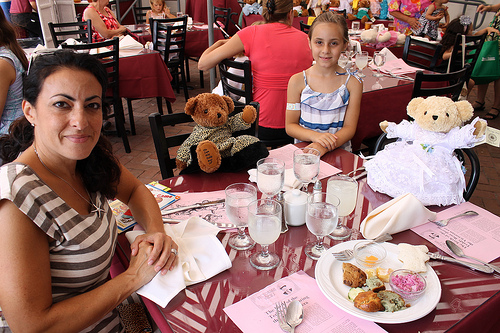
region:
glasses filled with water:
[232, 180, 292, 255]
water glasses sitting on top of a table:
[226, 158, 283, 265]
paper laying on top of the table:
[151, 179, 221, 220]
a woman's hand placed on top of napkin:
[123, 230, 187, 285]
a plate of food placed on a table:
[311, 258, 423, 328]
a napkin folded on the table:
[372, 197, 420, 253]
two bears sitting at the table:
[168, 91, 480, 185]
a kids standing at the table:
[307, 40, 371, 145]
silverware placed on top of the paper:
[271, 292, 301, 330]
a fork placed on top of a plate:
[326, 241, 351, 265]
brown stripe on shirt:
[13, 178, 40, 205]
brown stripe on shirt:
[26, 193, 53, 220]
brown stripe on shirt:
[41, 203, 68, 230]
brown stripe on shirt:
[49, 213, 79, 237]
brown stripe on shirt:
[4, 164, 18, 188]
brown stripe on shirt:
[106, 323, 123, 332]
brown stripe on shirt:
[88, 312, 113, 330]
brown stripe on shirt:
[51, 281, 102, 295]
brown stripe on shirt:
[49, 270, 108, 285]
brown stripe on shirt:
[46, 257, 112, 276]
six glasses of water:
[223, 145, 358, 270]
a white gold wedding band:
[168, 245, 178, 255]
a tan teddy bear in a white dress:
[362, 94, 499, 206]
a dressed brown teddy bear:
[174, 93, 269, 175]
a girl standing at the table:
[283, 10, 362, 160]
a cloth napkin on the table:
[360, 191, 437, 241]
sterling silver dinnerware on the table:
[425, 210, 499, 275]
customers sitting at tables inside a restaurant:
[0, 0, 497, 331]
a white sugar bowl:
[282, 186, 306, 226]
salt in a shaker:
[309, 180, 322, 201]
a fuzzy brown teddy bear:
[174, 92, 267, 174]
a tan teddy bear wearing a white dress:
[364, 93, 482, 206]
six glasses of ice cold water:
[224, 145, 358, 268]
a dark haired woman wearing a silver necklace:
[0, 52, 180, 332]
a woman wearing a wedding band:
[0, 47, 177, 332]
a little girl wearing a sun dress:
[284, 8, 362, 160]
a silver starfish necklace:
[30, 140, 108, 217]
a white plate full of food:
[315, 236, 441, 321]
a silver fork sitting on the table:
[427, 210, 478, 227]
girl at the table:
[297, 24, 358, 149]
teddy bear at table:
[397, 105, 474, 205]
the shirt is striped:
[32, 223, 95, 268]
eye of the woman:
[45, 90, 72, 115]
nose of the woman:
[65, 115, 90, 132]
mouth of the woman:
[57, 128, 97, 143]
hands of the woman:
[130, 234, 189, 281]